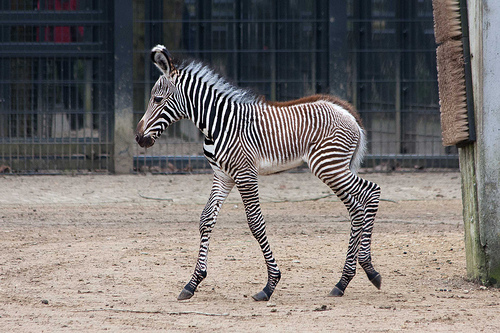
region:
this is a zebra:
[117, 30, 412, 297]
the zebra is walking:
[113, 35, 395, 316]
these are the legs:
[185, 171, 395, 295]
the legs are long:
[185, 173, 285, 293]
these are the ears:
[148, 42, 170, 71]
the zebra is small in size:
[260, 114, 305, 142]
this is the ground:
[32, 226, 170, 331]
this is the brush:
[432, 48, 470, 123]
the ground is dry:
[32, 217, 145, 323]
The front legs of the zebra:
[178, 184, 280, 301]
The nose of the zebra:
[135, 129, 145, 138]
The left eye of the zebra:
[151, 92, 161, 105]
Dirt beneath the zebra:
[3, 174, 497, 332]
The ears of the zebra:
[151, 40, 171, 71]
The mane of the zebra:
[177, 59, 259, 101]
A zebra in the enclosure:
[137, 45, 380, 299]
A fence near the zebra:
[1, 5, 458, 173]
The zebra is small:
[136, 46, 383, 303]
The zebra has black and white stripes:
[134, 45, 381, 302]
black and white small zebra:
[137, 45, 382, 301]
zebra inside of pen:
[139, 48, 384, 299]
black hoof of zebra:
[178, 289, 194, 299]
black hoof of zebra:
[253, 290, 271, 300]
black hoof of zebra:
[333, 286, 340, 295]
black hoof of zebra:
[374, 272, 382, 284]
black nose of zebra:
[133, 131, 154, 146]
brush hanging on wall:
[430, 10, 477, 143]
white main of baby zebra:
[181, 66, 256, 105]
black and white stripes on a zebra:
[195, 89, 228, 128]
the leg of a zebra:
[240, 183, 282, 292]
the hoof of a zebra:
[252, 288, 269, 303]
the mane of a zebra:
[185, 58, 253, 98]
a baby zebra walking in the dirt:
[122, 38, 402, 304]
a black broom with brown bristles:
[432, 3, 482, 145]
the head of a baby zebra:
[125, 38, 186, 158]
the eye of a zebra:
[155, 94, 166, 103]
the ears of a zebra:
[150, 43, 179, 77]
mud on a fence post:
[106, 56, 140, 174]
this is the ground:
[47, 242, 152, 317]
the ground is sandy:
[27, 212, 144, 319]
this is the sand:
[57, 197, 124, 282]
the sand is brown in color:
[29, 194, 147, 318]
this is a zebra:
[117, 38, 414, 322]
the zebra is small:
[118, 52, 427, 304]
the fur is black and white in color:
[226, 119, 276, 144]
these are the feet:
[166, 171, 388, 291]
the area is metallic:
[32, 23, 97, 103]